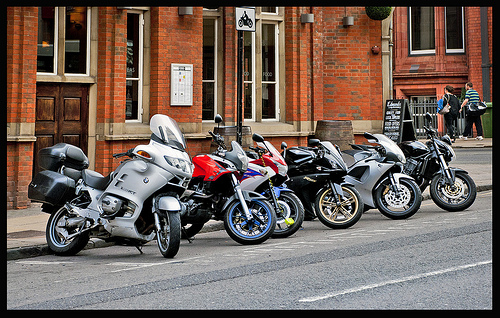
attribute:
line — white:
[298, 257, 496, 308]